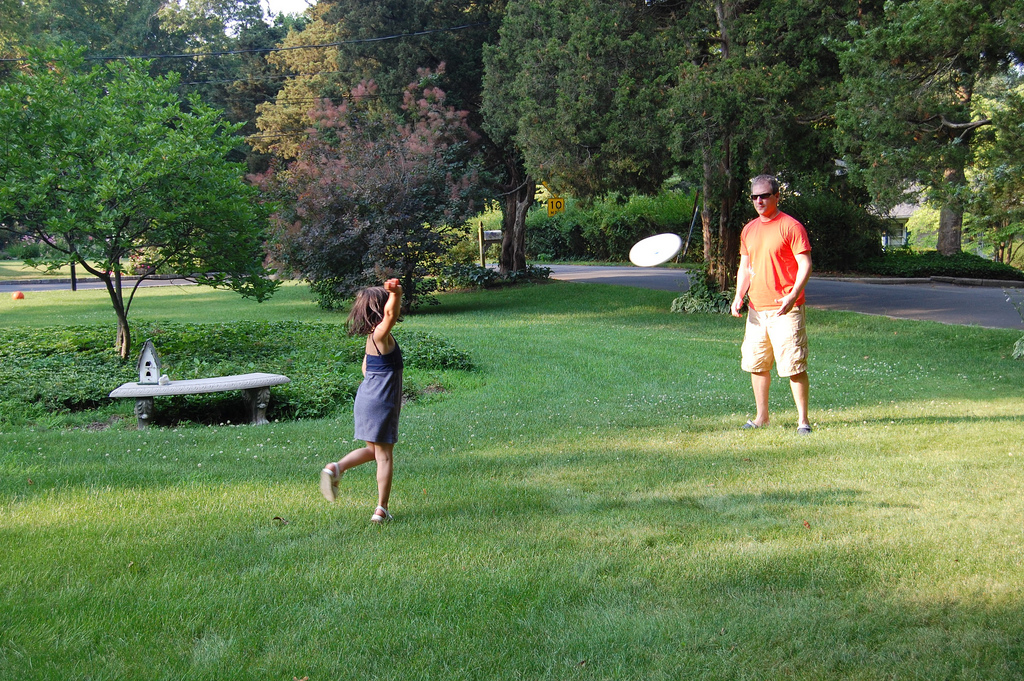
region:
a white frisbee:
[623, 228, 703, 263]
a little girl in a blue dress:
[284, 265, 444, 547]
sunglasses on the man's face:
[752, 192, 772, 209]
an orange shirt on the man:
[730, 202, 829, 317]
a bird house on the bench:
[132, 339, 167, 396]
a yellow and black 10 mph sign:
[546, 195, 570, 224]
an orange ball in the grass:
[12, 285, 28, 304]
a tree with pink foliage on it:
[268, 57, 499, 318]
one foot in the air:
[313, 446, 362, 513]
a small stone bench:
[106, 367, 304, 447]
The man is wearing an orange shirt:
[675, 142, 906, 550]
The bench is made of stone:
[109, 350, 404, 543]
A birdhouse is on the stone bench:
[45, 291, 298, 485]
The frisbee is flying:
[561, 108, 833, 422]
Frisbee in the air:
[623, 226, 682, 275]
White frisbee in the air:
[623, 226, 684, 271]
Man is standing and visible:
[722, 169, 830, 436]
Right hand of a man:
[773, 291, 799, 318]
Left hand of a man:
[722, 292, 749, 324]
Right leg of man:
[789, 377, 813, 422]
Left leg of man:
[743, 365, 772, 414]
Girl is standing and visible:
[313, 267, 422, 515]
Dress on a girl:
[346, 348, 407, 450]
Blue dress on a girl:
[348, 343, 410, 458]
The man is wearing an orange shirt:
[703, 152, 844, 446]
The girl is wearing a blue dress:
[327, 269, 403, 570]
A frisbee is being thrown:
[279, 162, 868, 565]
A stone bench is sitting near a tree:
[99, 347, 284, 425]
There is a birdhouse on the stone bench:
[114, 323, 176, 399]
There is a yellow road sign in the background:
[516, 163, 597, 241]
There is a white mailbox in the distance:
[454, 201, 512, 285]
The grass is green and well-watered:
[424, 380, 630, 627]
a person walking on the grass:
[307, 285, 431, 542]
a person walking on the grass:
[720, 165, 835, 438]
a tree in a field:
[13, 41, 273, 367]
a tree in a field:
[247, 57, 503, 320]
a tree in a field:
[837, 7, 1014, 263]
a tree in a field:
[951, 71, 1019, 258]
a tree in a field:
[256, 7, 560, 263]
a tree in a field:
[0, 0, 261, 144]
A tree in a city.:
[35, 83, 282, 385]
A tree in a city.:
[274, 68, 505, 373]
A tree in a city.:
[471, 20, 955, 312]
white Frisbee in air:
[619, 217, 680, 293]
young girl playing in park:
[329, 249, 421, 537]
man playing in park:
[720, 142, 834, 440]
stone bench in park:
[106, 371, 285, 428]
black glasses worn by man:
[755, 179, 775, 214]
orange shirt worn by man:
[733, 221, 823, 308]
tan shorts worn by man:
[745, 300, 810, 389]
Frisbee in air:
[622, 217, 680, 282]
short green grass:
[464, 510, 582, 575]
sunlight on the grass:
[878, 477, 936, 548]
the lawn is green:
[525, 443, 696, 602]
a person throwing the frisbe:
[328, 260, 445, 505]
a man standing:
[723, 184, 835, 434]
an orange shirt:
[748, 241, 796, 299]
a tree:
[101, 268, 147, 349]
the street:
[582, 255, 633, 297]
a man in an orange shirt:
[745, 180, 816, 433]